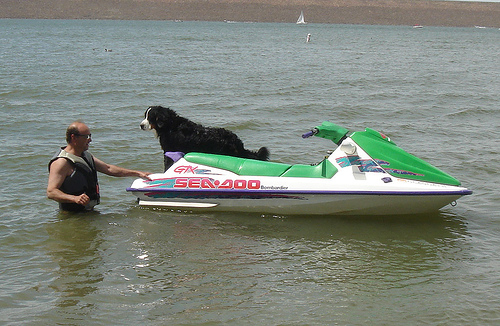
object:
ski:
[118, 115, 480, 225]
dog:
[127, 95, 281, 177]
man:
[36, 118, 155, 218]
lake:
[1, 19, 499, 325]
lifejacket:
[40, 143, 112, 215]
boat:
[289, 4, 314, 30]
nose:
[137, 119, 152, 132]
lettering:
[171, 175, 262, 191]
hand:
[133, 168, 155, 184]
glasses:
[72, 131, 95, 142]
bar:
[294, 125, 327, 140]